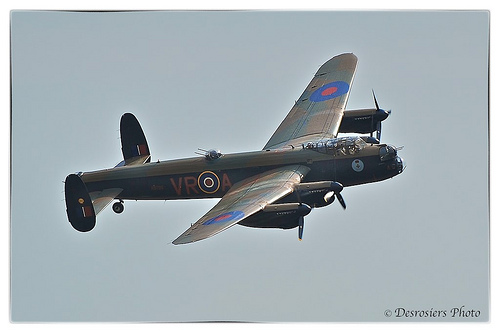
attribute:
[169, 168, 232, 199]
letters — black print style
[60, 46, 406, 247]
plane — jet, in air, flying, small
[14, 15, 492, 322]
sky — blue, cloudy, white